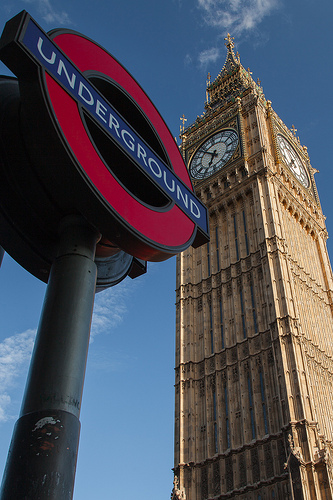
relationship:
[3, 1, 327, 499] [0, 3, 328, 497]
sky with clouds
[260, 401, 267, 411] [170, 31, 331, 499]
window on building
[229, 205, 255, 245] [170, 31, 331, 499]
window on building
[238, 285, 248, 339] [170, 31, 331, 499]
window on building